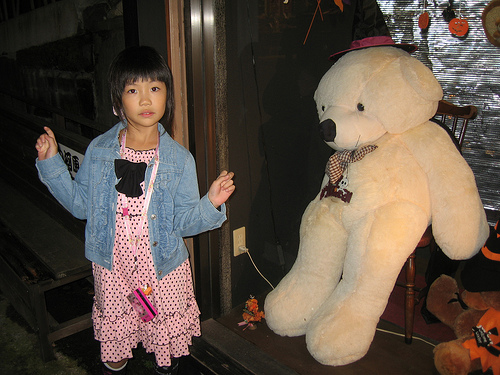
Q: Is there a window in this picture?
A: Yes, there is a window.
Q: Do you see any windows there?
A: Yes, there is a window.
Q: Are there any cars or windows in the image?
A: Yes, there is a window.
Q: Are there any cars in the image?
A: No, there are no cars.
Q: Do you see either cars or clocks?
A: No, there are no cars or clocks.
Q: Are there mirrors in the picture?
A: No, there are no mirrors.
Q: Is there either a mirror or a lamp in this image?
A: No, there are no mirrors or lamps.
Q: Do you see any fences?
A: No, there are no fences.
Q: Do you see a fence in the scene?
A: No, there are no fences.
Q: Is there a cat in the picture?
A: No, there are no cats.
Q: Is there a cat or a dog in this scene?
A: No, there are no cats or dogs.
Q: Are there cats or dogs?
A: No, there are no cats or dogs.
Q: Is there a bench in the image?
A: Yes, there is a bench.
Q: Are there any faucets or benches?
A: Yes, there is a bench.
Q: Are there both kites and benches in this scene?
A: No, there is a bench but no kites.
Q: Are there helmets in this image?
A: No, there are no helmets.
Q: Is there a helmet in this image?
A: No, there are no helmets.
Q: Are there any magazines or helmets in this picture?
A: No, there are no helmets or magazines.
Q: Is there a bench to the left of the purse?
A: Yes, there is a bench to the left of the purse.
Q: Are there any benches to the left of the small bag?
A: Yes, there is a bench to the left of the purse.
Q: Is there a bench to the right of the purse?
A: No, the bench is to the left of the purse.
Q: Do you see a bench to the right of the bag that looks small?
A: No, the bench is to the left of the purse.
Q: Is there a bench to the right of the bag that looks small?
A: No, the bench is to the left of the purse.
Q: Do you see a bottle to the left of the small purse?
A: No, there is a bench to the left of the purse.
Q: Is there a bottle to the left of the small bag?
A: No, there is a bench to the left of the purse.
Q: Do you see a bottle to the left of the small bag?
A: No, there is a bench to the left of the purse.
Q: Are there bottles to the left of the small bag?
A: No, there is a bench to the left of the purse.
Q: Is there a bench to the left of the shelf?
A: Yes, there is a bench to the left of the shelf.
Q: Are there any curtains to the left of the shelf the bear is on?
A: No, there is a bench to the left of the shelf.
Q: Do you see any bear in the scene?
A: Yes, there is a bear.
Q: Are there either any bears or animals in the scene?
A: Yes, there is a bear.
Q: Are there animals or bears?
A: Yes, there is a bear.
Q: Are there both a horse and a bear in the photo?
A: No, there is a bear but no horses.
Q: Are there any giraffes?
A: No, there are no giraffes.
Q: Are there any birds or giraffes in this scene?
A: No, there are no giraffes or birds.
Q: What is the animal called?
A: The animal is a bear.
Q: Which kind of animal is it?
A: The animal is a bear.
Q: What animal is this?
A: That is a bear.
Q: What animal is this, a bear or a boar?
A: That is a bear.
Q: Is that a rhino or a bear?
A: That is a bear.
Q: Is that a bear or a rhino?
A: That is a bear.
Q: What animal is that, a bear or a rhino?
A: That is a bear.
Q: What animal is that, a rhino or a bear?
A: That is a bear.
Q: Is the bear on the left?
A: No, the bear is on the right of the image.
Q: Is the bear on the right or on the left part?
A: The bear is on the right of the image.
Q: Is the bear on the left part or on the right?
A: The bear is on the right of the image.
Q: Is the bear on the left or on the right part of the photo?
A: The bear is on the right of the image.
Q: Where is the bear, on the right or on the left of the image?
A: The bear is on the right of the image.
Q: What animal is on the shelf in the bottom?
A: The bear is on the shelf.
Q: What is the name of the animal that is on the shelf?
A: The animal is a bear.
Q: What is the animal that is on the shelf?
A: The animal is a bear.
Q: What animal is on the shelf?
A: The animal is a bear.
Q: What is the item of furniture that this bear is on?
A: The piece of furniture is a shelf.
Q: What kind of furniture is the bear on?
A: The bear is on the shelf.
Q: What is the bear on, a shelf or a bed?
A: The bear is on a shelf.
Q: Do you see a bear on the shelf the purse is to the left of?
A: Yes, there is a bear on the shelf.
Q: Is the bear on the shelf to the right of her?
A: Yes, the bear is on the shelf.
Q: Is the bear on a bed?
A: No, the bear is on the shelf.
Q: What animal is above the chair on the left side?
A: The animal is a bear.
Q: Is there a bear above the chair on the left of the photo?
A: Yes, there is a bear above the chair.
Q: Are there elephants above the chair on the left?
A: No, there is a bear above the chair.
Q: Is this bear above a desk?
A: No, the bear is above a chair.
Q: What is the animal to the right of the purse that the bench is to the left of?
A: The animal is a bear.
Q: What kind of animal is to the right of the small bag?
A: The animal is a bear.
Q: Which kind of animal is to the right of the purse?
A: The animal is a bear.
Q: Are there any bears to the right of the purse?
A: Yes, there is a bear to the right of the purse.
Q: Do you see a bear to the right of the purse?
A: Yes, there is a bear to the right of the purse.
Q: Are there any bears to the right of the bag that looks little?
A: Yes, there is a bear to the right of the purse.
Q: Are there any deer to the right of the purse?
A: No, there is a bear to the right of the purse.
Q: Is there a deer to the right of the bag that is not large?
A: No, there is a bear to the right of the purse.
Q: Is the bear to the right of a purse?
A: Yes, the bear is to the right of a purse.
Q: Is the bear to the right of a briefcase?
A: No, the bear is to the right of a purse.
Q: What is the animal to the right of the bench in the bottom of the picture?
A: The animal is a bear.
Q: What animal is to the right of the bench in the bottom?
A: The animal is a bear.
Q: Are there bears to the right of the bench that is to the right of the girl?
A: Yes, there is a bear to the right of the bench.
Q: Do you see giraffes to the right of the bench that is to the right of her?
A: No, there is a bear to the right of the bench.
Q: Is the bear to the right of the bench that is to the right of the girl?
A: Yes, the bear is to the right of the bench.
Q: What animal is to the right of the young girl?
A: The animal is a bear.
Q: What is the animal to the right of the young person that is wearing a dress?
A: The animal is a bear.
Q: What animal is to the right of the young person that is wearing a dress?
A: The animal is a bear.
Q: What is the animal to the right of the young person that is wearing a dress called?
A: The animal is a bear.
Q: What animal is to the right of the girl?
A: The animal is a bear.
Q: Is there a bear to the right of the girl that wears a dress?
A: Yes, there is a bear to the right of the girl.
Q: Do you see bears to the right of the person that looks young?
A: Yes, there is a bear to the right of the girl.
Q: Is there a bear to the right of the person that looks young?
A: Yes, there is a bear to the right of the girl.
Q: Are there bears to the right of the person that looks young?
A: Yes, there is a bear to the right of the girl.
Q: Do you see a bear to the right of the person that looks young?
A: Yes, there is a bear to the right of the girl.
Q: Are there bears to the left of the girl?
A: No, the bear is to the right of the girl.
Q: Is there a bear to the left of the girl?
A: No, the bear is to the right of the girl.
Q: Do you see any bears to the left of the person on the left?
A: No, the bear is to the right of the girl.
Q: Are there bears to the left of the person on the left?
A: No, the bear is to the right of the girl.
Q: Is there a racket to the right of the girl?
A: No, there is a bear to the right of the girl.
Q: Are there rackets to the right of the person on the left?
A: No, there is a bear to the right of the girl.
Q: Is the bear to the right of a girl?
A: Yes, the bear is to the right of a girl.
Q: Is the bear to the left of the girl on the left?
A: No, the bear is to the right of the girl.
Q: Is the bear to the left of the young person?
A: No, the bear is to the right of the girl.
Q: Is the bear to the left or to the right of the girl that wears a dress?
A: The bear is to the right of the girl.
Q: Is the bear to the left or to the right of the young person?
A: The bear is to the right of the girl.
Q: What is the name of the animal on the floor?
A: The animal is a bear.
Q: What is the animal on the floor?
A: The animal is a bear.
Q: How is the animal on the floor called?
A: The animal is a bear.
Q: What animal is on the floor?
A: The animal is a bear.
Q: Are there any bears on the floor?
A: Yes, there is a bear on the floor.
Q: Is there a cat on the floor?
A: No, there is a bear on the floor.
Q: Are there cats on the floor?
A: No, there is a bear on the floor.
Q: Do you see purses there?
A: Yes, there is a purse.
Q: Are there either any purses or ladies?
A: Yes, there is a purse.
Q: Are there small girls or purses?
A: Yes, there is a small purse.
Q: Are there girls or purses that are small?
A: Yes, the purse is small.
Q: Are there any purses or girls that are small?
A: Yes, the purse is small.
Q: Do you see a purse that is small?
A: Yes, there is a small purse.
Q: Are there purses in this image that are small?
A: Yes, there is a purse that is small.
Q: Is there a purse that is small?
A: Yes, there is a purse that is small.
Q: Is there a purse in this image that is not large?
A: Yes, there is a small purse.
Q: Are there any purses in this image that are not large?
A: Yes, there is a small purse.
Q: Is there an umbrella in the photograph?
A: No, there are no umbrellas.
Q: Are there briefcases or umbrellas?
A: No, there are no umbrellas or briefcases.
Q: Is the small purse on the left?
A: Yes, the purse is on the left of the image.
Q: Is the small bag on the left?
A: Yes, the purse is on the left of the image.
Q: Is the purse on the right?
A: No, the purse is on the left of the image.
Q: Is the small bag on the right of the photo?
A: No, the purse is on the left of the image.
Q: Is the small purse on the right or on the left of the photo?
A: The purse is on the left of the image.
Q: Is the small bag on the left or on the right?
A: The purse is on the left of the image.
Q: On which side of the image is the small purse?
A: The purse is on the left of the image.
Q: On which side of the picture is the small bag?
A: The purse is on the left of the image.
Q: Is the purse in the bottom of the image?
A: Yes, the purse is in the bottom of the image.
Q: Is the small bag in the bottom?
A: Yes, the purse is in the bottom of the image.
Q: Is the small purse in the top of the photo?
A: No, the purse is in the bottom of the image.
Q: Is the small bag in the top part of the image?
A: No, the purse is in the bottom of the image.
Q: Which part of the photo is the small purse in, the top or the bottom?
A: The purse is in the bottom of the image.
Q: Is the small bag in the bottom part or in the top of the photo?
A: The purse is in the bottom of the image.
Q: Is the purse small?
A: Yes, the purse is small.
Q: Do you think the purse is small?
A: Yes, the purse is small.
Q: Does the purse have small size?
A: Yes, the purse is small.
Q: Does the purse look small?
A: Yes, the purse is small.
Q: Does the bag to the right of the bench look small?
A: Yes, the purse is small.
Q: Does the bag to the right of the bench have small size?
A: Yes, the purse is small.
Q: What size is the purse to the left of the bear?
A: The purse is small.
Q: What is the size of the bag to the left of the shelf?
A: The purse is small.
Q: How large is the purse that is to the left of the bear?
A: The purse is small.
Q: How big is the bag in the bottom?
A: The purse is small.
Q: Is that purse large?
A: No, the purse is small.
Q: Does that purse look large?
A: No, the purse is small.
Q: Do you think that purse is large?
A: No, the purse is small.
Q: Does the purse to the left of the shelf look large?
A: No, the purse is small.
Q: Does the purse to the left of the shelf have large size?
A: No, the purse is small.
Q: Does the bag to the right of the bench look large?
A: No, the purse is small.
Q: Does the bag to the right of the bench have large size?
A: No, the purse is small.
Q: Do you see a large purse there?
A: No, there is a purse but it is small.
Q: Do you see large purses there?
A: No, there is a purse but it is small.